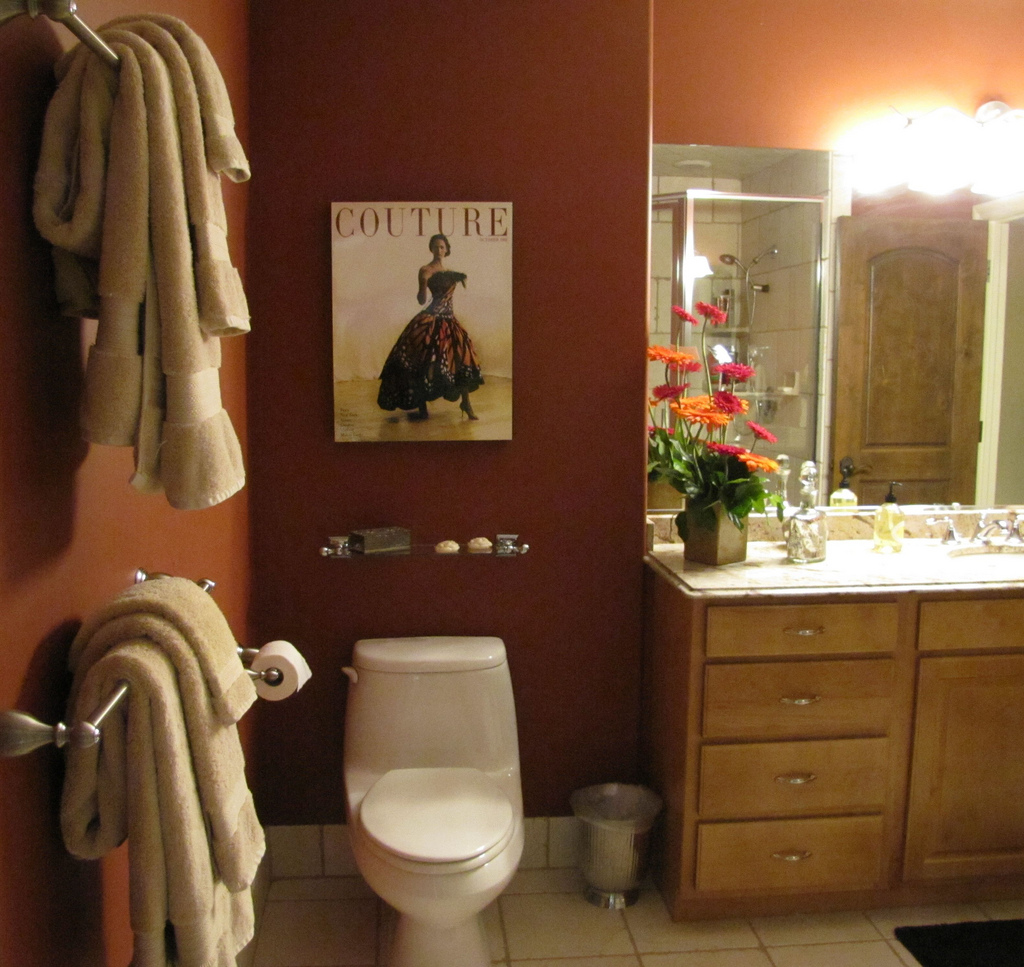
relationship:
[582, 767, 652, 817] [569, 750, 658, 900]
bag inside can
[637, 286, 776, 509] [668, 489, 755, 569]
flowers in vase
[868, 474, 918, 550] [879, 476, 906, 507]
lotion dispenser with nozzle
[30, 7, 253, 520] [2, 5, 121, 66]
towel on towel rack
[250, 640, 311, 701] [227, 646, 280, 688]
dispenser on holder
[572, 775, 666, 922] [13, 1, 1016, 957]
can in bathroom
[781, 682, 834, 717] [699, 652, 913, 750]
handle on drawer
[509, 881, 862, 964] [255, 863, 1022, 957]
tiles on floor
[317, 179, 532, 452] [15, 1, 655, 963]
picture on wall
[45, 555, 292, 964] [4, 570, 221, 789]
towel on rack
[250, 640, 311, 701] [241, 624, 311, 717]
dispenser on roll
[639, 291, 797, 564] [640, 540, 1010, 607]
flowers on counter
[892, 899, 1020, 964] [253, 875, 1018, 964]
rug on floor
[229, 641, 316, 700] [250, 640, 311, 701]
dispenser has dispenser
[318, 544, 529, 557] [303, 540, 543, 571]
shelf on shelf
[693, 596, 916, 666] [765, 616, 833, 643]
drawer has handle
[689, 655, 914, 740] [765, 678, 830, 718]
drawer has handle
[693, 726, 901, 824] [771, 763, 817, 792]
drawer has handle